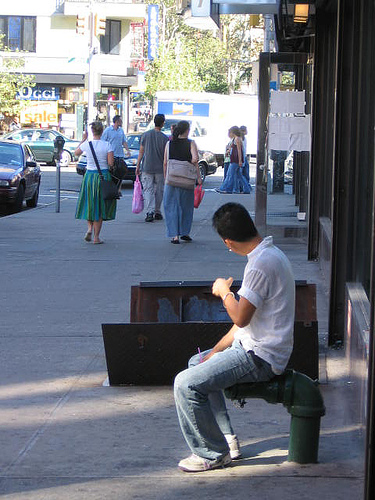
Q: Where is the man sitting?
A: Outside of a business.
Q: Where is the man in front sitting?
A: On a pipe.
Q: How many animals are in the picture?
A: 0.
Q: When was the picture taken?
A: In day time.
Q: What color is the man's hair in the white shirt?
A: Black.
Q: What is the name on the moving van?
A: Budget.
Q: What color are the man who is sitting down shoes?
A: White.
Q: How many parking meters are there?
A: 1.